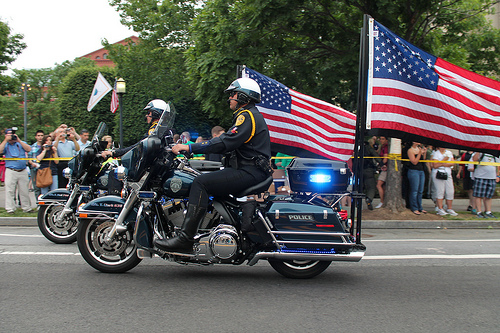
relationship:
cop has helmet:
[216, 70, 277, 120] [183, 70, 270, 108]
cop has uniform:
[152, 78, 276, 255] [195, 108, 281, 200]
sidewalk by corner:
[376, 206, 439, 245] [2, 201, 56, 250]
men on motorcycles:
[50, 82, 311, 258] [112, 156, 226, 248]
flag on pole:
[352, 22, 484, 175] [348, 40, 384, 179]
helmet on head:
[183, 70, 270, 108] [221, 92, 261, 109]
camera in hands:
[8, 126, 34, 145] [0, 127, 50, 143]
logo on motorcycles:
[278, 210, 322, 238] [112, 156, 226, 248]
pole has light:
[348, 40, 384, 179] [9, 71, 46, 147]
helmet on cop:
[183, 70, 270, 108] [152, 78, 276, 255]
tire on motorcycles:
[41, 201, 69, 249] [112, 156, 226, 248]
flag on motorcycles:
[352, 22, 484, 175] [112, 156, 226, 248]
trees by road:
[153, 12, 278, 73] [49, 211, 361, 333]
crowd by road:
[1, 112, 458, 175] [49, 211, 361, 333]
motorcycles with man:
[112, 156, 226, 248] [3, 88, 97, 156]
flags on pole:
[83, 71, 141, 122] [348, 40, 384, 179]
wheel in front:
[83, 198, 138, 266] [16, 165, 170, 266]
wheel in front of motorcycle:
[83, 198, 138, 266] [79, 140, 366, 286]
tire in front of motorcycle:
[41, 201, 69, 249] [79, 140, 366, 286]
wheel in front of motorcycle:
[83, 198, 138, 266] [60, 134, 360, 276]